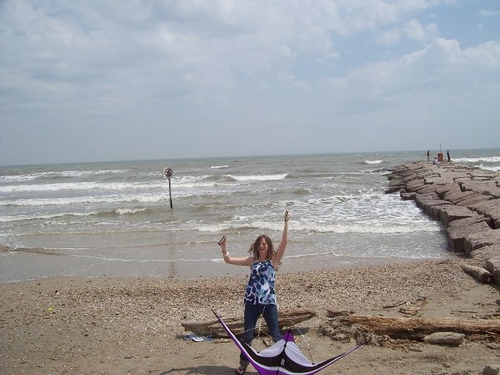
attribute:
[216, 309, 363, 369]
kite — purple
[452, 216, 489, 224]
stone — grey, large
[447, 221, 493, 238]
stone — grey, large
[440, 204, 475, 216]
stone — grey, large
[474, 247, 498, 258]
stone — grey, large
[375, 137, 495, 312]
jetty — rock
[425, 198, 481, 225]
stone — large, grey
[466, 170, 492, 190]
stone — large, grey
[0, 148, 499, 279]
water — gray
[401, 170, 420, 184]
stone — large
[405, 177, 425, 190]
stone — grey, large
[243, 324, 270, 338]
string — white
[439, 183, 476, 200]
stone — large, grey, colored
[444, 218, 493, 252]
stone — large, grey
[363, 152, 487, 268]
stone — large, grey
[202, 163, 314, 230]
water — murky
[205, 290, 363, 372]
kite — upside down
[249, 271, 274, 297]
shirt. — patterned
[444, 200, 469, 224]
stone — large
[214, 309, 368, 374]
kite — purple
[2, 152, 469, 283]
water — brown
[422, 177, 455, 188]
stone — large, grey, colored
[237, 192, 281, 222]
water — murky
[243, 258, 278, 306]
pattern — blue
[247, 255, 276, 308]
shirt — blue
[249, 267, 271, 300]
print — blue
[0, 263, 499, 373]
sand — light brown